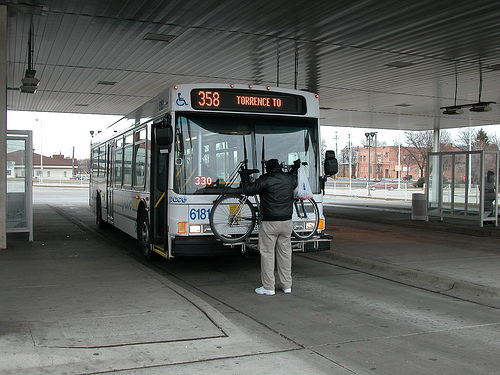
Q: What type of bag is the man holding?
A: Plastic.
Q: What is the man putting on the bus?
A: Bicycle.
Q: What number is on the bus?
A: 358.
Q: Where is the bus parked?
A: Bus station.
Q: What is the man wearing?
A: Black jacket.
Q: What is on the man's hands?
A: Gloves.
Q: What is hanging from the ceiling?
A: Lights.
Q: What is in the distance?
A: Buildings.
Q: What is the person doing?
A: Standing in front of the bus.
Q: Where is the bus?
A: Next to sidewalk.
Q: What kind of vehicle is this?
A: Bus.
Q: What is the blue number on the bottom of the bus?
A: 6181.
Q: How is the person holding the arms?
A: Up and towards the bus.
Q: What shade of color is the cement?
A: Grey.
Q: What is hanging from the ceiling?
A: Lights.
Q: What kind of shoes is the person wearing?
A: Sneakers.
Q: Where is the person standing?
A: Bus terminal.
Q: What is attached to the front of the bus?
A: Bicycle.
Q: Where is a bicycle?
A: In front of the bus.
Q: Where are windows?
A: On the bus.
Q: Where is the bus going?
A: Torrence.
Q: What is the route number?
A: 358.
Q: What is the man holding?
A: A bike.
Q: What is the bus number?
A: 6181.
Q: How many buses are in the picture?
A: 1.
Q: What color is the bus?
A: White.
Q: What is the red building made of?
A: Brick.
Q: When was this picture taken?
A: Daytime.